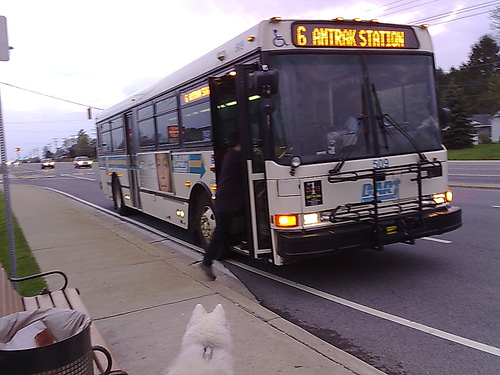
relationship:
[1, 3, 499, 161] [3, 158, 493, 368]
sky above street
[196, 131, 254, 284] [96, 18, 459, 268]
person getting in bus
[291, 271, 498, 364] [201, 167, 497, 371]
line on ground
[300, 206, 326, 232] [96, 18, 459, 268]
light on bus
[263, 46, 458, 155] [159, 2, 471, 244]
window on bus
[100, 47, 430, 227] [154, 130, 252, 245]
person on bus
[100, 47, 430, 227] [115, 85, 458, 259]
person on bus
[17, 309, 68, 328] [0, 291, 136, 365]
bag in can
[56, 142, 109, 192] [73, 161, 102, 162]
head lights on car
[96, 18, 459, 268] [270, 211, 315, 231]
bus has headlights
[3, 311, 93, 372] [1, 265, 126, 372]
garbage can next to bench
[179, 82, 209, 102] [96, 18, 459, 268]
light on bus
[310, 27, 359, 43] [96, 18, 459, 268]
light on bus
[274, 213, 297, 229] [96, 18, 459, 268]
light on bus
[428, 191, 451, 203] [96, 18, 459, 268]
light on bus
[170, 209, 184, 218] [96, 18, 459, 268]
light on bus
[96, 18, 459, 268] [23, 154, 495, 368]
bus parked on road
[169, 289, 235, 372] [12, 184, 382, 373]
dog on sidewalk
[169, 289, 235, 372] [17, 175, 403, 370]
dog sitting on sidewalk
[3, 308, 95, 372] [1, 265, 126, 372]
trash can next to bench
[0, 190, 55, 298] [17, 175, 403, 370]
grass by sidewalk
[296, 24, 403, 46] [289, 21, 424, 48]
letters on sign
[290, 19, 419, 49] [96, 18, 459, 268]
sign on bus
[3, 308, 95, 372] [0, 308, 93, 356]
trash can has top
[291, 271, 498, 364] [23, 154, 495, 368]
line on road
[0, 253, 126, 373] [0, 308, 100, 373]
bench by can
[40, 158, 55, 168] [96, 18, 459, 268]
car behind bus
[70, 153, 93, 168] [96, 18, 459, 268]
car behind bus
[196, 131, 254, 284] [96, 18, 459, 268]
person getting on bus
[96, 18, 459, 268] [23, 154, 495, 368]
bus on side of road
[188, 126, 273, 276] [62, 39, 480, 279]
passenger on bus